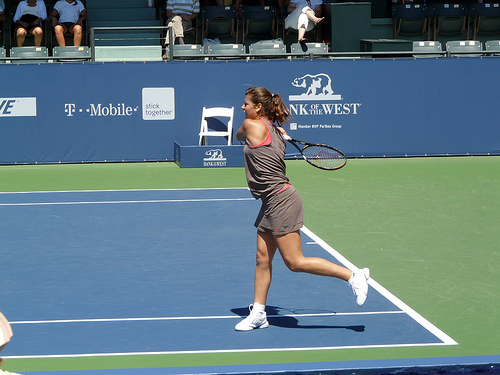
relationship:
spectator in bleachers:
[283, 2, 327, 45] [2, 0, 499, 59]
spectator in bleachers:
[163, 0, 203, 57] [2, 0, 499, 59]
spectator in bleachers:
[50, 0, 85, 47] [2, 0, 499, 59]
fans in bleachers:
[13, 1, 47, 47] [2, 0, 499, 59]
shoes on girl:
[231, 259, 391, 339] [222, 86, 354, 296]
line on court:
[2, 310, 403, 325] [0, 156, 497, 374]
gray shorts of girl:
[253, 183, 313, 238] [236, 87, 370, 330]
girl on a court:
[236, 87, 370, 330] [0, 153, 499, 375]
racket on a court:
[277, 127, 349, 171] [0, 156, 497, 374]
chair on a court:
[196, 104, 237, 150] [0, 156, 497, 374]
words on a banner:
[33, 90, 185, 131] [0, 57, 498, 162]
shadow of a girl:
[227, 297, 369, 340] [236, 87, 370, 330]